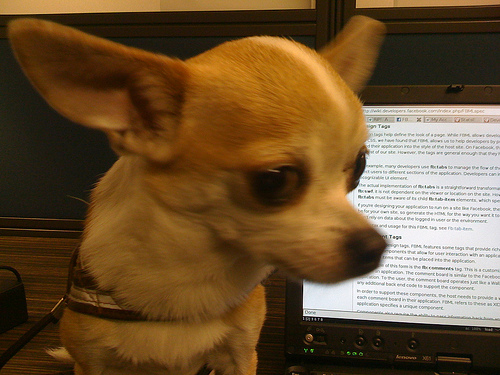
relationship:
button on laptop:
[407, 332, 419, 352] [253, 86, 495, 371]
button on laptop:
[370, 334, 384, 350] [253, 86, 495, 371]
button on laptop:
[351, 332, 366, 349] [253, 86, 495, 371]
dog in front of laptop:
[9, 0, 384, 371] [275, 78, 500, 374]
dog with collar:
[9, 0, 384, 371] [51, 266, 265, 331]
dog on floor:
[9, 0, 384, 371] [3, 205, 335, 372]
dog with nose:
[9, 0, 384, 371] [344, 227, 388, 273]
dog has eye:
[9, 0, 384, 371] [242, 157, 307, 209]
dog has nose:
[9, 0, 384, 371] [335, 218, 402, 280]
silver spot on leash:
[49, 295, 69, 320] [0, 242, 204, 370]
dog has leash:
[9, 0, 384, 371] [3, 294, 74, 366]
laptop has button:
[275, 78, 500, 374] [296, 331, 313, 348]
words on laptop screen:
[346, 107, 498, 324] [299, 101, 499, 333]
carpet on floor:
[15, 231, 63, 285] [2, 237, 284, 374]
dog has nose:
[9, 0, 384, 371] [347, 226, 390, 271]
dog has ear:
[9, 0, 384, 371] [316, 10, 387, 92]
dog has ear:
[9, 0, 384, 371] [0, 10, 185, 160]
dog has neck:
[9, 0, 384, 371] [83, 155, 275, 316]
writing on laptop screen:
[363, 129, 498, 156] [299, 104, 500, 333]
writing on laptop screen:
[348, 121, 500, 322] [299, 104, 500, 333]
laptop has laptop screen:
[275, 70, 497, 374] [299, 104, 500, 333]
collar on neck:
[66, 239, 211, 327] [115, 218, 245, 303]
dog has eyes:
[9, 0, 384, 371] [240, 143, 371, 199]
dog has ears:
[9, 0, 384, 371] [39, 20, 202, 159]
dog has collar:
[9, 0, 384, 371] [65, 257, 156, 321]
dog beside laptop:
[9, 0, 384, 371] [275, 70, 497, 374]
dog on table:
[9, 0, 384, 371] [0, 230, 97, 367]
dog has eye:
[9, 14, 391, 371] [219, 129, 336, 223]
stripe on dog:
[237, 32, 354, 150] [9, 14, 391, 371]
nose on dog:
[288, 216, 397, 289] [80, 39, 450, 344]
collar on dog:
[66, 261, 211, 328] [9, 0, 384, 371]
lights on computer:
[293, 342, 376, 361] [242, 85, 498, 369]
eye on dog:
[245, 161, 307, 206] [9, 0, 384, 371]